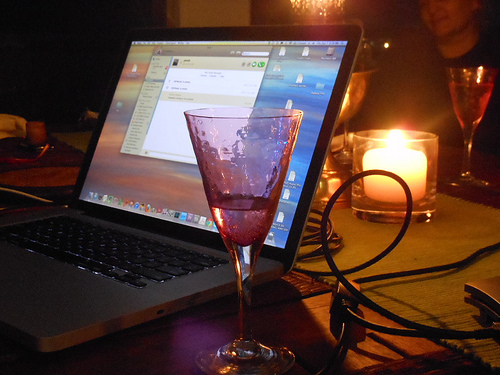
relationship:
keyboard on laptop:
[1, 215, 231, 288] [1, 24, 365, 352]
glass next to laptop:
[184, 106, 304, 374] [1, 24, 365, 352]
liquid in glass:
[209, 195, 275, 247] [184, 106, 304, 374]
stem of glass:
[220, 233, 266, 360] [184, 106, 304, 374]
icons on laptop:
[86, 190, 221, 231] [1, 24, 365, 352]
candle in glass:
[362, 126, 427, 205] [350, 129, 438, 224]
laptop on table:
[1, 24, 365, 352] [1, 122, 499, 372]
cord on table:
[297, 169, 500, 374] [1, 122, 499, 372]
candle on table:
[362, 126, 427, 205] [1, 122, 499, 372]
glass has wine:
[446, 64, 498, 187] [450, 80, 494, 130]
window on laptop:
[120, 47, 273, 167] [1, 24, 365, 352]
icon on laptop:
[101, 194, 109, 203] [1, 24, 365, 352]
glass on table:
[184, 106, 304, 374] [1, 122, 499, 372]